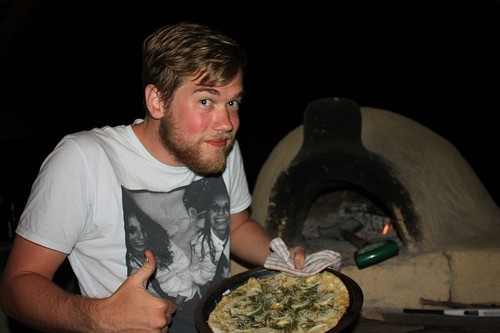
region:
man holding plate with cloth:
[4, 20, 389, 331]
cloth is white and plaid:
[252, 225, 349, 297]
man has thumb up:
[58, 233, 185, 331]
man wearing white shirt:
[10, 110, 289, 317]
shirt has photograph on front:
[90, 150, 270, 330]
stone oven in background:
[218, 79, 498, 319]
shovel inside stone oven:
[289, 198, 423, 293]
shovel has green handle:
[307, 205, 407, 285]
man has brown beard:
[150, 91, 239, 186]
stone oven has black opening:
[260, 78, 441, 243]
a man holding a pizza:
[50, 91, 320, 330]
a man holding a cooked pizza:
[111, 33, 453, 329]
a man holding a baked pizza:
[36, 69, 479, 329]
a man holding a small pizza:
[89, 76, 374, 312]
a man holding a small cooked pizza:
[57, 72, 360, 328]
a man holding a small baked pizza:
[72, 41, 333, 317]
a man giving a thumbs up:
[64, 70, 343, 329]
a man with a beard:
[26, 64, 315, 329]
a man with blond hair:
[78, 18, 343, 196]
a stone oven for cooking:
[219, 48, 456, 330]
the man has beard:
[132, 40, 254, 195]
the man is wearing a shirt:
[20, 118, 305, 329]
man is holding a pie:
[176, 215, 335, 332]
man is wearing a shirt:
[37, 99, 251, 331]